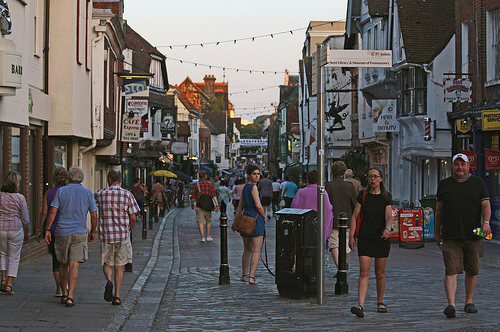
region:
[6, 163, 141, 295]
they are walking together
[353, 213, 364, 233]
the purse is red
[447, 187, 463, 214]
the shirt is black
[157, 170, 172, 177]
the umbrella is yellow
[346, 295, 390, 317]
she is wearing sandles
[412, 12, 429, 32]
the roof is brown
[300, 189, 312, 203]
the shaw is pink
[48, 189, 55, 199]
the shirt is purple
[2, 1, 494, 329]
people walking on a road bounded by buildings on both sides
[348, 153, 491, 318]
man and woman both stepping forward with their right feet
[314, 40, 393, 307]
location-style signs on a metal post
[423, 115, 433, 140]
red and white barber's pole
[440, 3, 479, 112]
sign hung from a bar outside a building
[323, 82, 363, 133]
dark figure of a winged creature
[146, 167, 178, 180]
a large yellow umbrella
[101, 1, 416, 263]
string lights suspended above street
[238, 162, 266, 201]
woman looking back over her shoulder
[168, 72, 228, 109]
sunlight shining on building in the distance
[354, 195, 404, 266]
the dress is black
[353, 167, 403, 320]
the woman has glasses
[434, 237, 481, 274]
the shorts are brown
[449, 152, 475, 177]
the hat is white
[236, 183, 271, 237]
the dress is blue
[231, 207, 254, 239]
the bag is brown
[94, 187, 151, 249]
the shirt is checked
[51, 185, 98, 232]
the shirt is blue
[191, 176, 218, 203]
the shirt is black and red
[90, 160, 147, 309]
Man in red and white checkered shirt.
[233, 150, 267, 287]
Woman carrying brown purse.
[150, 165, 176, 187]
Yellow umbrella in front of building.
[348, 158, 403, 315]
Woman carrying a red purse.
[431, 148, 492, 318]
Man wearing a white cap.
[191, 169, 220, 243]
Man wearing red and black shirt.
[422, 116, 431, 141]
Pipe with red and white stripes hanging outside of building.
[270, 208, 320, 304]
Green box near street pole.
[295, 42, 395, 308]
Sliver colored with pole with white street signs.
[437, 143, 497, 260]
a person on the sidewalk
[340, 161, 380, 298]
a person on the sidewalk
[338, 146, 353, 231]
a person on the sidewalk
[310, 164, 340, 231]
a person on the sidewalk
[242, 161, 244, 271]
a person on the sidewalk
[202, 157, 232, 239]
a person on the sidewalk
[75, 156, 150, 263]
a person on the sidewalk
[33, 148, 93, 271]
a person on the sidewalk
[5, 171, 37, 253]
a person on the sidewalk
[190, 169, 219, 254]
a person on the sidewalk